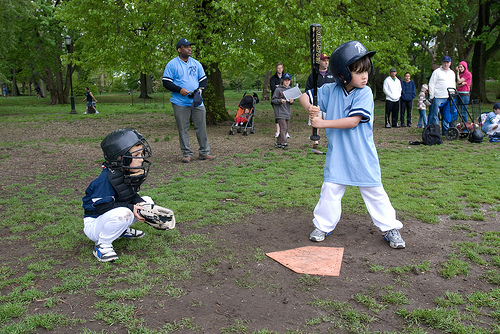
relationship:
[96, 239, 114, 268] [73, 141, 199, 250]
blue shoe of kid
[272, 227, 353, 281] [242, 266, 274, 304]
homeplate on ground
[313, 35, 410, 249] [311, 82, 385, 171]
boy in shirt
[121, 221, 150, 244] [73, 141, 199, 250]
shoe of kid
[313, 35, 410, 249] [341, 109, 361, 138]
boy has left elbow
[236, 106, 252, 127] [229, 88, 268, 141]
child in stroller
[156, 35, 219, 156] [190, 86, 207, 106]
man holding mitt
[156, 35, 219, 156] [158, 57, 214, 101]
man in blue shirt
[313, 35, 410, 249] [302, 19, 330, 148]
boy holding baseball bat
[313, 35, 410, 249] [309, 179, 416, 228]
boy wearing white pants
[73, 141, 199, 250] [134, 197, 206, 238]
kid holding catchers mitt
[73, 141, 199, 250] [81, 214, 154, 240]
kid in white pants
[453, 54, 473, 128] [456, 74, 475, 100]
lady in pink shirt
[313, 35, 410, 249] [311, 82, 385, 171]
boy in blue shirt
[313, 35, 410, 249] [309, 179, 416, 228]
boy in white pants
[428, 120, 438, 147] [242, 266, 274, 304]
backpack on ground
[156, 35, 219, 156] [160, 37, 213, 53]
man in hat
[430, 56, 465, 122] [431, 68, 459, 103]
guy in white shirt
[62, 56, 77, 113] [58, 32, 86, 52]
post with light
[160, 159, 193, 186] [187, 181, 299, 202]
patches of grass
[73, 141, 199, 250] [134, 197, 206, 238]
kid wearing catchers mitt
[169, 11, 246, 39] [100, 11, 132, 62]
tree has green leaves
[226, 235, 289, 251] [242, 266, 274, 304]
dirt on ground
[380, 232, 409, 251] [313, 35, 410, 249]
foot of boy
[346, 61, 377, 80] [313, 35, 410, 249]
head of boy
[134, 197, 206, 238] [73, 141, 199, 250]
catchers mitt on kid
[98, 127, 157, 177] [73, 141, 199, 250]
catchers mask on kid